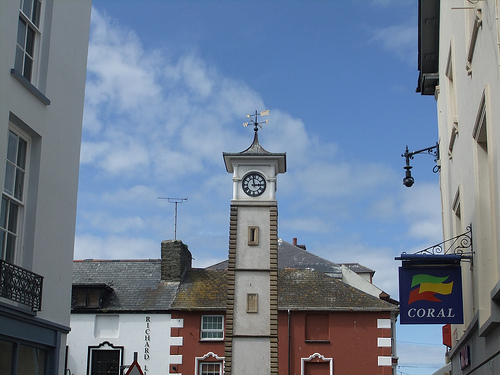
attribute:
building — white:
[5, 0, 103, 370]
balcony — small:
[109, 293, 406, 318]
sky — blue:
[90, 51, 427, 273]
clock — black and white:
[239, 171, 267, 197]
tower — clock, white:
[218, 99, 287, 372]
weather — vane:
[72, 0, 442, 305]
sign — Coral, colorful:
[397, 257, 465, 329]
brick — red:
[378, 327, 393, 339]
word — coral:
[406, 307, 455, 318]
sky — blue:
[228, 5, 388, 116]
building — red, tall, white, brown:
[79, 244, 395, 374]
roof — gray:
[74, 258, 177, 312]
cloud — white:
[169, 53, 216, 106]